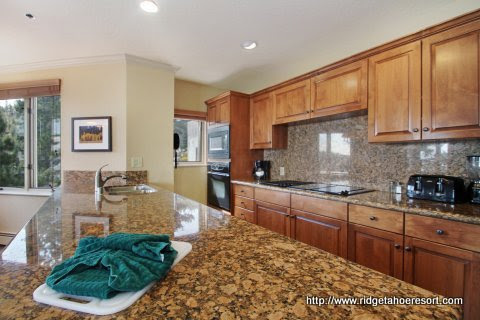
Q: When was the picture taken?
A: Daytime.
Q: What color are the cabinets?
A: Brown.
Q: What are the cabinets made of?
A: Wood.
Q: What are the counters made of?
A: Marble.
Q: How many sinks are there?
A: One.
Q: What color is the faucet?
A: Silver.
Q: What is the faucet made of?
A: Metal.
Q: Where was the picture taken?
A: In a kitchen.